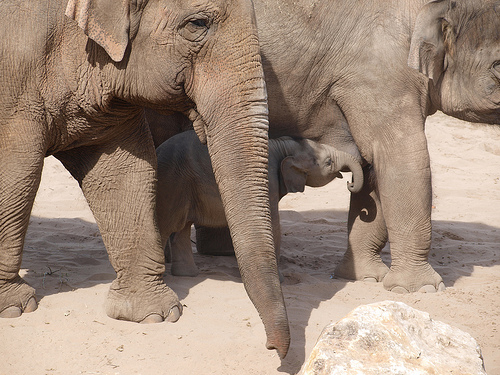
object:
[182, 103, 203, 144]
mouth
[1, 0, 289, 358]
elephant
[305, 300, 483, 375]
rock